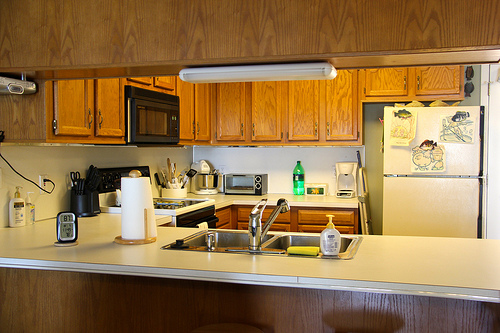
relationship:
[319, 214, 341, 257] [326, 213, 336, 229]
soap has yellow top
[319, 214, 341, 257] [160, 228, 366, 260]
soap on sink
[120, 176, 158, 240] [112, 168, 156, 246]
paper towel in holder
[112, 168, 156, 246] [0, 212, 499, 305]
holder on countertop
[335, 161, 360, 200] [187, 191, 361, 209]
coffee maker on countertop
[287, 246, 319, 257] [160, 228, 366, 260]
sponge on sink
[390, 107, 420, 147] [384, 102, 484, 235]
drawing on refrigerator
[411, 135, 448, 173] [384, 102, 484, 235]
drawing on refrigerator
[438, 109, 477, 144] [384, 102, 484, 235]
drawing on refrigerator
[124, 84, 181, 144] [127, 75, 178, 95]
microwave underneath cabinet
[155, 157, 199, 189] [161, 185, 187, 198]
utensils in container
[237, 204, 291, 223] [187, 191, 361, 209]
drawer below counter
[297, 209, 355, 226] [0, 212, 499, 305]
drawer below countertop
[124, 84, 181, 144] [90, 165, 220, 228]
microwave over stove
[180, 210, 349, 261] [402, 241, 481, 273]
sink set into counter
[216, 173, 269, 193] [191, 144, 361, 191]
appliance against wall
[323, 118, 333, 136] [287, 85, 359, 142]
handle on cabinet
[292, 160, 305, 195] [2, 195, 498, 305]
bottle on top of countertop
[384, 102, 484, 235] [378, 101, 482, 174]
refrigerator has a refrigerator door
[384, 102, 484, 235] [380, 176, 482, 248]
refrigerator has a refrigerator door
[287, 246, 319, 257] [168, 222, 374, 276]
sponge by sink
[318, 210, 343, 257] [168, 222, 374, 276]
soap by sink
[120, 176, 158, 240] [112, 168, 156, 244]
paper towel in a holder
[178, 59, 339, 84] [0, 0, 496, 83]
light underneath cabinet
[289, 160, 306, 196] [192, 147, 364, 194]
bottle against a wall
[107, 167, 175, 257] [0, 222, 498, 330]
paper towel on counter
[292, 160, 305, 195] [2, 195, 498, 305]
bottle on countertop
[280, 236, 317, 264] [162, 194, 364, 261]
sponge on sink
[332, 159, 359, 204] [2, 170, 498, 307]
coffee maker on counter top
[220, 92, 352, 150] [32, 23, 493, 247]
cabinets on wall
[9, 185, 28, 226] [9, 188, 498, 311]
bottle on counter top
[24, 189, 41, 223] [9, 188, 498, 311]
bottle on counter top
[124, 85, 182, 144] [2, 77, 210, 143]
microwave next to cabinets